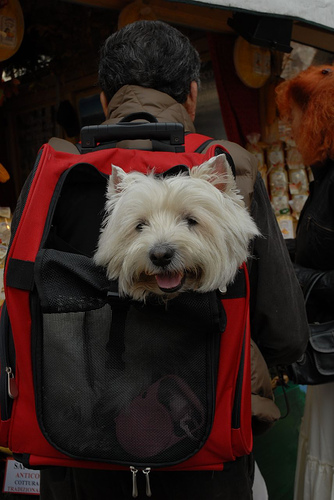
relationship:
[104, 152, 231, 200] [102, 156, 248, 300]
ears on dog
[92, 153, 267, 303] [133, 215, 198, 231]
dog has eyes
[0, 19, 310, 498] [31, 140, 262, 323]
man wearing backpack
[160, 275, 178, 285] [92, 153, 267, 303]
tougne of dog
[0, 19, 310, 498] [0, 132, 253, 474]
man carrying back pack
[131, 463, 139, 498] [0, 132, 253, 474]
zipper on back pack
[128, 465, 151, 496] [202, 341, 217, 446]
zipper handles for zipper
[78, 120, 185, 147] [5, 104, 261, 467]
handle on bag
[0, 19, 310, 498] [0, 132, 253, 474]
man with back pack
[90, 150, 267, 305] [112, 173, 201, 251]
head of dog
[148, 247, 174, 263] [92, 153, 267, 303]
nose of dog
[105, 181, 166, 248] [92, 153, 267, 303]
fur of dog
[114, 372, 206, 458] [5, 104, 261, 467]
leash behind bag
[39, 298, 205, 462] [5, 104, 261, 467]
pocket on bag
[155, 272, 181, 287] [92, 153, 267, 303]
tongue on dog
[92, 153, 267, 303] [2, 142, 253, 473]
dog inside backpack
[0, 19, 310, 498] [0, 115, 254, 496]
man wearing backpack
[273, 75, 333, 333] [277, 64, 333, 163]
woman with hair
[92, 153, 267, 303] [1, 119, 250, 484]
dog riding in dog/backpack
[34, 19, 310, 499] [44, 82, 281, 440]
man wearing brown vest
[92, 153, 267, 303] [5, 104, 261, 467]
dog in bag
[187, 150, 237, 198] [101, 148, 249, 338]
ear of dog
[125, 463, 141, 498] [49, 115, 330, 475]
zipper on back pack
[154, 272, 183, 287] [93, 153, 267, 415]
tongue of dog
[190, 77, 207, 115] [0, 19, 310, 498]
ear of man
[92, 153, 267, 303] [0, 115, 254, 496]
dog in backpack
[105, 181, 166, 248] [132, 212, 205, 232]
fur covering eyes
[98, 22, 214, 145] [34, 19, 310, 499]
head of man